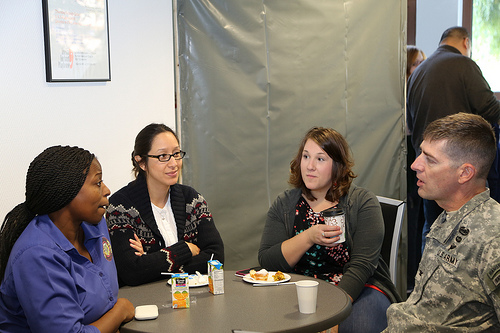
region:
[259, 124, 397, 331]
A woman holding a cup.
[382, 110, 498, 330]
A man in a military uniform.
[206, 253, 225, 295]
A carton of juice.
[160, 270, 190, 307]
A carton of juice.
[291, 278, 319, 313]
A small white cup.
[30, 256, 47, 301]
Part of a blue shirt.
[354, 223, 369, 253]
Part of a grey shirt.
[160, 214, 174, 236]
Part of a white shirt.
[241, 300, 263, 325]
Part of the table.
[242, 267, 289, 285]
A plate of food.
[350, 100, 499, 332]
Soldier in cammo uniform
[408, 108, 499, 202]
Head of dining soldier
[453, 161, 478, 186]
Ear of dining soldier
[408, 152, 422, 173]
Nose of dining soldier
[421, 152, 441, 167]
Eye of dining soldier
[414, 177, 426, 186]
Mouth of dining soldier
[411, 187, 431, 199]
Chin of dining soldier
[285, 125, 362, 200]
Head of dining woman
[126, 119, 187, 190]
Head of dining woman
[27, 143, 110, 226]
Head of dining woman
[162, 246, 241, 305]
straws stuck in juice boxes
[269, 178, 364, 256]
a woman holding a cut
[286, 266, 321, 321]
a cup sitting on a table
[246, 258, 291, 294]
food served on a white plate.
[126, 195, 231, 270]
a woman crossing her arms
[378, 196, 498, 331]
a man wearing an army uniform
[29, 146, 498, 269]
people engaging in conversation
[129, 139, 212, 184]
a woman wearing eyeglasses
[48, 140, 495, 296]
people sitting at a table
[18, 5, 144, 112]
a picture hanging on a wall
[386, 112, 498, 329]
A man is wearing an army uniform.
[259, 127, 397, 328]
A woman in gray is holding a cup.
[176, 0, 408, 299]
Gray plastic is on a wall.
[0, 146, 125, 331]
A woman is talking.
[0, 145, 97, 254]
The woman has braided hair.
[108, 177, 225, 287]
The person is wearing a sweater.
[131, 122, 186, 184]
The woman is wearing glasses.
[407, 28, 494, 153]
A man in a gray shirt is looking down.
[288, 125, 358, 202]
The head has brown hair.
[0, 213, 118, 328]
A woman is wearing a blue shirt.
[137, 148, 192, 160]
a woman's black eyeglasses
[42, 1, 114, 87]
part of a black picture frame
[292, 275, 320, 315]
a white paper cup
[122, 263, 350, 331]
part of a round gray table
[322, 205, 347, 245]
a black and white coffee cup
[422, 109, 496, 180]
a man's short cut hair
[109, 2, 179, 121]
part of a white painted wall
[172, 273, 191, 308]
a juice carton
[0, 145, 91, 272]
a woman's braided hair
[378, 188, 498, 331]
part of an army uniform